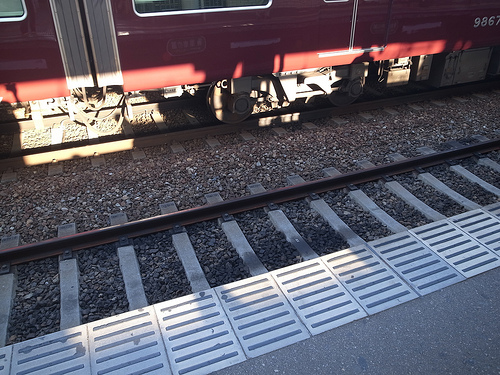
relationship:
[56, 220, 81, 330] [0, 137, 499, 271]
tie under rail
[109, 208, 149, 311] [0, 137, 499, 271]
tie under rail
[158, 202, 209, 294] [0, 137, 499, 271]
tie under rail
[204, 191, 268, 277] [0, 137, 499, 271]
tie under rail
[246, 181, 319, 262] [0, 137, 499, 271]
tie under rail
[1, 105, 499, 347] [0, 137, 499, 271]
gravel under rail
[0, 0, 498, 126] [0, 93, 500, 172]
train on top of tracks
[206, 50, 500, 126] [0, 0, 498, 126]
machinery under train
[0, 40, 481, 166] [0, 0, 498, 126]
sunlight illuminating train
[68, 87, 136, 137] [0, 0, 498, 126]
cables hanging under train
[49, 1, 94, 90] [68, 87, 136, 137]
panel above cables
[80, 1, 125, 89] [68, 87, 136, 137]
panel above cables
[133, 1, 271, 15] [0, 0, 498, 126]
window located on train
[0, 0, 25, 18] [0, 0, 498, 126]
window located on train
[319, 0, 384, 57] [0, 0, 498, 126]
line painted on train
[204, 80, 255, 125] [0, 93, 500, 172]
wheel on top of tracks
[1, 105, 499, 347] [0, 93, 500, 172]
gravel near tracks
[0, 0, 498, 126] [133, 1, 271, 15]
train has window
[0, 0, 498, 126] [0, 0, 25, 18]
train has window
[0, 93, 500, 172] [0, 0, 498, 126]
tracks under train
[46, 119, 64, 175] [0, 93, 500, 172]
tie under tracks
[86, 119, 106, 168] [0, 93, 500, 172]
tie under tracks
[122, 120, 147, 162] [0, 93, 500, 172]
tie under tracks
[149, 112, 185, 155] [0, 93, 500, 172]
tie under tracks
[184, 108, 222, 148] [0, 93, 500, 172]
tie under tracks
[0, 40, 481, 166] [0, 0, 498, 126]
sunlight shining on train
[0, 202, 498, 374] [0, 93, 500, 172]
platform near tracks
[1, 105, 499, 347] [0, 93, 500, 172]
gravel around tracks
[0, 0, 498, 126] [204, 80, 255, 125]
train has wheel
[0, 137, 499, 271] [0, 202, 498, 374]
rail near platform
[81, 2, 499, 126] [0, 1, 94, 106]
train car connected to train car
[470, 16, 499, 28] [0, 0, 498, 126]
numbers printed on train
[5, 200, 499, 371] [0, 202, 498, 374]
rectangles on edge of platform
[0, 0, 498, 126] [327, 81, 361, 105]
train has wheel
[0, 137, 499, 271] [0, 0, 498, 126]
rail next to train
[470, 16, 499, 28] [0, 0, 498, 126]
numbers on side of train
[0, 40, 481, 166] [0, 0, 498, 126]
sunlight reflected on train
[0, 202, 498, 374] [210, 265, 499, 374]
platform has pavement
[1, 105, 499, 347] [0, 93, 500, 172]
gravel between tracks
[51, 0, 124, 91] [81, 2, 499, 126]
connector next to train car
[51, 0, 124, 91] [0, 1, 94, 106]
connector next to train car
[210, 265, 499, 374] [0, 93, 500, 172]
pavement next to tracks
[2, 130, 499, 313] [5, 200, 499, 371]
line of rectangles